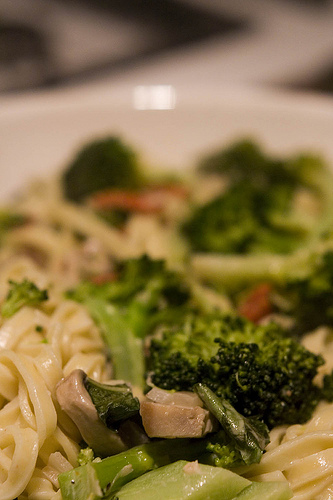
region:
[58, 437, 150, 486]
this is a green vegetable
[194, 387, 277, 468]
this is a green vegetable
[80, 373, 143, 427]
this is a green vegetable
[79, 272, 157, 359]
this is a green vegetable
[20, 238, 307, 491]
this is a meal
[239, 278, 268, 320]
this is a red vegetable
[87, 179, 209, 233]
this is a red vegetable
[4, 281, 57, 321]
this is a green vegetable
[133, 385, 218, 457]
this is brown in colour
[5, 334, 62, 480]
this is cream in colour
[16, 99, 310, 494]
a white plate full of some food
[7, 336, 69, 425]
a bunch of pasta stuck together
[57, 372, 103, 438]
a small bite sized piece of mushroom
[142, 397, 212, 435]
a small little piece of chicken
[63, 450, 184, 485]
a small piece of broccolli stem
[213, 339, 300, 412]
a large piece of a broccolis bush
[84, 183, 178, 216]
a single strip of red vegetable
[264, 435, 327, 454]
a single piece of white noodle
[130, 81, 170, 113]
the light shining down on the plate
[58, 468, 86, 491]
a small speck of broccoli bush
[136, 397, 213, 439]
The meat is brown.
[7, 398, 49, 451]
The noodles are white.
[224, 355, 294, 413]
The broccoli is green.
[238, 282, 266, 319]
The food on the plate is red.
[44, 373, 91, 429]
The mushrooms are grey.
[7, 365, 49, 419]
The noodles are on the plate.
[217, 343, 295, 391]
The broccoli is on the plate.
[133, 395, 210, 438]
The meat is on the plate.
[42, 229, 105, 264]
The noodles in the background are blurry.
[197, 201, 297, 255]
The broccoli in the background is blurry.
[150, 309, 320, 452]
a piece of cooked broccoli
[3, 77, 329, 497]
a plate of food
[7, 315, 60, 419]
shiny beige cooked noodles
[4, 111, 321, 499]
plate of noodles and broccoli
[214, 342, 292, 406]
dark green broccoli florets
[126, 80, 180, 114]
light reflecting on the plate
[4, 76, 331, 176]
white plate the food is on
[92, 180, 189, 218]
blurry orange food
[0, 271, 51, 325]
very small piece of broccoli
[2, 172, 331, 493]
shiny food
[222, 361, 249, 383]
broccoli on the plate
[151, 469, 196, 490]
broccoli on the plate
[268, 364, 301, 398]
broccoli on the plate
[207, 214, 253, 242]
broccoli on the plate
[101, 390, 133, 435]
broccoli on the plate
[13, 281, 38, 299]
broccoli on the plate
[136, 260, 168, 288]
broccoli on the plate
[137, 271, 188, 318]
broccoli on the plate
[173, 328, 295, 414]
broccoli on the plate